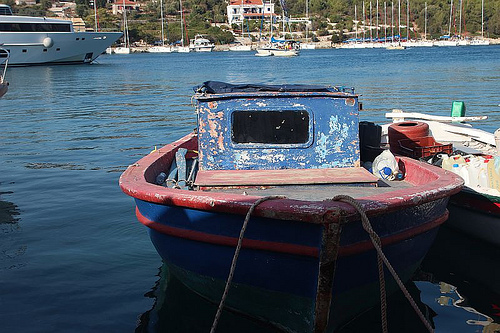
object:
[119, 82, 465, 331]
boat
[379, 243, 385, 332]
rope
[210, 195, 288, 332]
rope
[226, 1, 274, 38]
house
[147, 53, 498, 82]
lake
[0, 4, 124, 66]
yacht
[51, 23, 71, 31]
black windows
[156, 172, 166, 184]
bottle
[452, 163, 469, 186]
bottle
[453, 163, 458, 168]
blue cap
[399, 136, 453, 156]
red crate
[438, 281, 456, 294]
sludge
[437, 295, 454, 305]
sludge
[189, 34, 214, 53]
boat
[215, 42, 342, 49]
shore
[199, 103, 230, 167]
peeling paint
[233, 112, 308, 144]
window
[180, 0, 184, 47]
mast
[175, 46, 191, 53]
boat